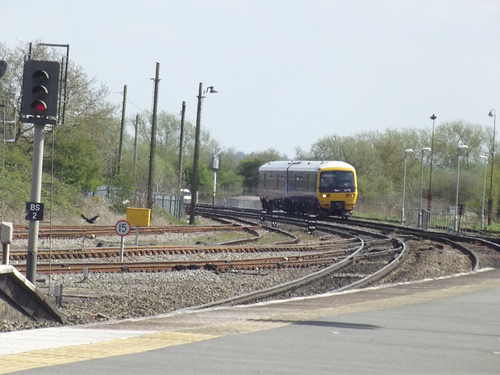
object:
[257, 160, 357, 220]
train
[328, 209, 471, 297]
track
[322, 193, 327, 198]
head light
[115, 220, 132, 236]
sign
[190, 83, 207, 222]
pole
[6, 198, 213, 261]
track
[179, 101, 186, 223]
pole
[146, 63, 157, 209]
pole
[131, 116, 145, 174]
pole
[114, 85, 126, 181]
pole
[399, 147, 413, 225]
pole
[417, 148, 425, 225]
pole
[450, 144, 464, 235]
pole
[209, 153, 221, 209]
pole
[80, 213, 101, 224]
bird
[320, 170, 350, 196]
windshield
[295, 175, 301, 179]
window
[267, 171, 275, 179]
window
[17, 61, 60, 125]
traffic signal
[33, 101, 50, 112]
red circle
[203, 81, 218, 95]
light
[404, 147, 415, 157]
light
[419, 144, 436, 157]
light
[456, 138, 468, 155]
light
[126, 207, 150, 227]
box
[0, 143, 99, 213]
bushes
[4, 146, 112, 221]
hill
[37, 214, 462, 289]
tracks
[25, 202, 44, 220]
sign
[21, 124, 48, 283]
pole